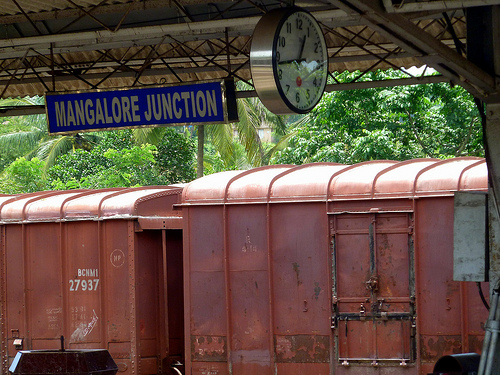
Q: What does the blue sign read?
A: Mangalore Junction.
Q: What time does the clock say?
A: 12:43.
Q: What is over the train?
A: Awning.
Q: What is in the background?
A: Trees.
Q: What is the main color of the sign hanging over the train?
A: Blue.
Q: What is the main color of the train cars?
A: Red.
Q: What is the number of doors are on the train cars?
A: 1.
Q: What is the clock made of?
A: Metal.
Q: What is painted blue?
A: A street sign.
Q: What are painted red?
A: The train cars.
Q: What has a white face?
A: The clock.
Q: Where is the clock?
A: Hanging from the ceiling.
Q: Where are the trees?
A: Behind the train.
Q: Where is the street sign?
A: Behind the clock.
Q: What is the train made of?
A: Metal.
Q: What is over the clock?
A: The roof of the building.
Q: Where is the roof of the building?
A: Over the clock.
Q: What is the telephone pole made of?
A: Wood.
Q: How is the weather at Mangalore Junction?
A: Clear.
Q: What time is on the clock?
A: 12:44.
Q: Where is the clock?
A: Attached to the ceiling.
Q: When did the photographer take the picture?
A: On vacation.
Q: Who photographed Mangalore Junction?
A: A tourist.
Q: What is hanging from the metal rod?
A: Mangalore Junction sign.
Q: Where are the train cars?
A: On railroad tracks.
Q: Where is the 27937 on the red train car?
A: The side.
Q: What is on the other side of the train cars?
A: Top of green trees.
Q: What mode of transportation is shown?
A: Train.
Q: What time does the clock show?
A: 12:44.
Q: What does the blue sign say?
A: Mangalore Junction.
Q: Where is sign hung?
A: From the ceiling.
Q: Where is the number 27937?
A: Second visible car.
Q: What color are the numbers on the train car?
A: White.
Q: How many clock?
A: One.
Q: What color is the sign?
A: Blue.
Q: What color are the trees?
A: Green.